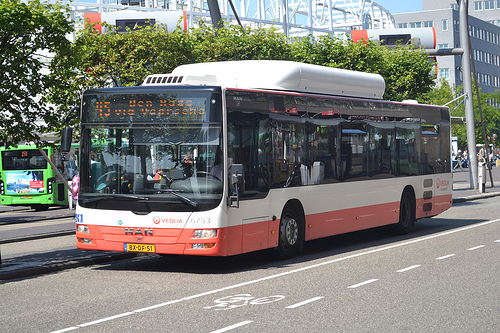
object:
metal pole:
[453, 1, 481, 192]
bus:
[69, 59, 456, 263]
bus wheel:
[274, 208, 304, 259]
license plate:
[121, 240, 154, 254]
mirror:
[228, 160, 244, 208]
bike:
[201, 292, 283, 313]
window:
[305, 115, 345, 185]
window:
[234, 110, 289, 201]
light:
[190, 227, 218, 242]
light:
[74, 221, 93, 233]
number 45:
[93, 99, 114, 118]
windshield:
[80, 89, 222, 211]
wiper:
[77, 190, 148, 202]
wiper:
[157, 168, 199, 207]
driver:
[207, 153, 235, 183]